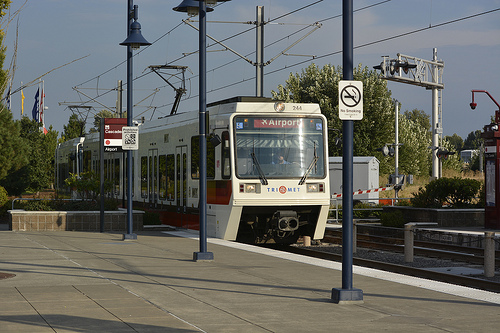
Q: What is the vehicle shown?
A: A tram.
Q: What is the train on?
A: Tracks.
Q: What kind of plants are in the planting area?
A: Green plants.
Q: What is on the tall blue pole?
A: A light.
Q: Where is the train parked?
A: A platform.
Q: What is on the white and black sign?
A: No smoking.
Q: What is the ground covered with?
A: Cement.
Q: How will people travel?
A: On the train.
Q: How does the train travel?
A: On tracks.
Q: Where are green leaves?
A: On trees.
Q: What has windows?
A: The train.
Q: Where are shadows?
A: On the ground.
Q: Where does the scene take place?
A: On a train platform.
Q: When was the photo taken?
A: During the daytime.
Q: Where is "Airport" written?
A: On red sign on the train window.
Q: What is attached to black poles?
A: White signs.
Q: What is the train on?
A: Train tracks.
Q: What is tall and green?
A: The trees.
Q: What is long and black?
A: Electric wires.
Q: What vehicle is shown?
A: A train.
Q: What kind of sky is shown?
A: Blue and cloudless.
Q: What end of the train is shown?
A: The front end.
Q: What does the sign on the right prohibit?
A: Smoking.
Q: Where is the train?
A: On tracks.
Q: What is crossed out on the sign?
A: A cigarette.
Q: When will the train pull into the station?
A: Shortly.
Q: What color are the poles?
A: Black.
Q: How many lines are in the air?
A: 4.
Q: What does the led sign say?
A: Airport.